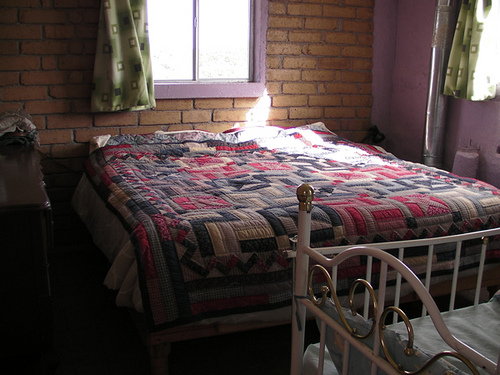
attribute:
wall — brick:
[273, 9, 367, 136]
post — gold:
[289, 180, 317, 371]